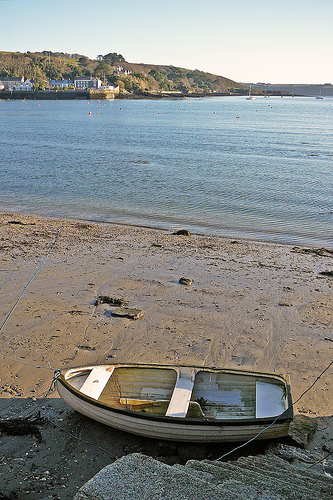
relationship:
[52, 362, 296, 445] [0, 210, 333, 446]
boat on shore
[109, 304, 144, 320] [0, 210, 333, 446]
rock on shore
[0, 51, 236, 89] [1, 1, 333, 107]
mountain in background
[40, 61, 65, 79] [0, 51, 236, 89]
trees on mountain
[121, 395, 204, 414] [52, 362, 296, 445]
oars in boat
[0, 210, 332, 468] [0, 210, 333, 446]
sand on shore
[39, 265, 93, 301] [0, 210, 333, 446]
sand on shore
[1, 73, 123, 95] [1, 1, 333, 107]
buildings in background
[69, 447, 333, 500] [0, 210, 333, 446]
steps lead to shore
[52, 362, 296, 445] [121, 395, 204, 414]
boat holds oars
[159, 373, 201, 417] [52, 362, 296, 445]
seat in boat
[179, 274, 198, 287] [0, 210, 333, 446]
rock on shore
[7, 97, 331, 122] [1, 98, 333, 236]
buoys in body of water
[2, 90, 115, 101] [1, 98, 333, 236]
wall next to body of water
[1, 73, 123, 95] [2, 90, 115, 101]
buildings next to wall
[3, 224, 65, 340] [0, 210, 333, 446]
rope on shore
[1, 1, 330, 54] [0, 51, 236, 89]
sky above mountain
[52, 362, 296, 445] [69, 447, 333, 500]
boat next to steps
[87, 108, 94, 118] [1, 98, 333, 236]
buoy in body of water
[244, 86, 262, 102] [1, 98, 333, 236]
sailboat in body of water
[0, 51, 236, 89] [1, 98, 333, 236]
mountain beside body of water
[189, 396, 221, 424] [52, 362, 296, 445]
rudder on boat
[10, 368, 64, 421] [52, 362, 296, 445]
rope tied to boat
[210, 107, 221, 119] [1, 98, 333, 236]
buoy in body of water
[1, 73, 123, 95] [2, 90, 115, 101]
buildings behind wall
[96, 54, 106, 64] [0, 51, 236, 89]
building on top of mountain